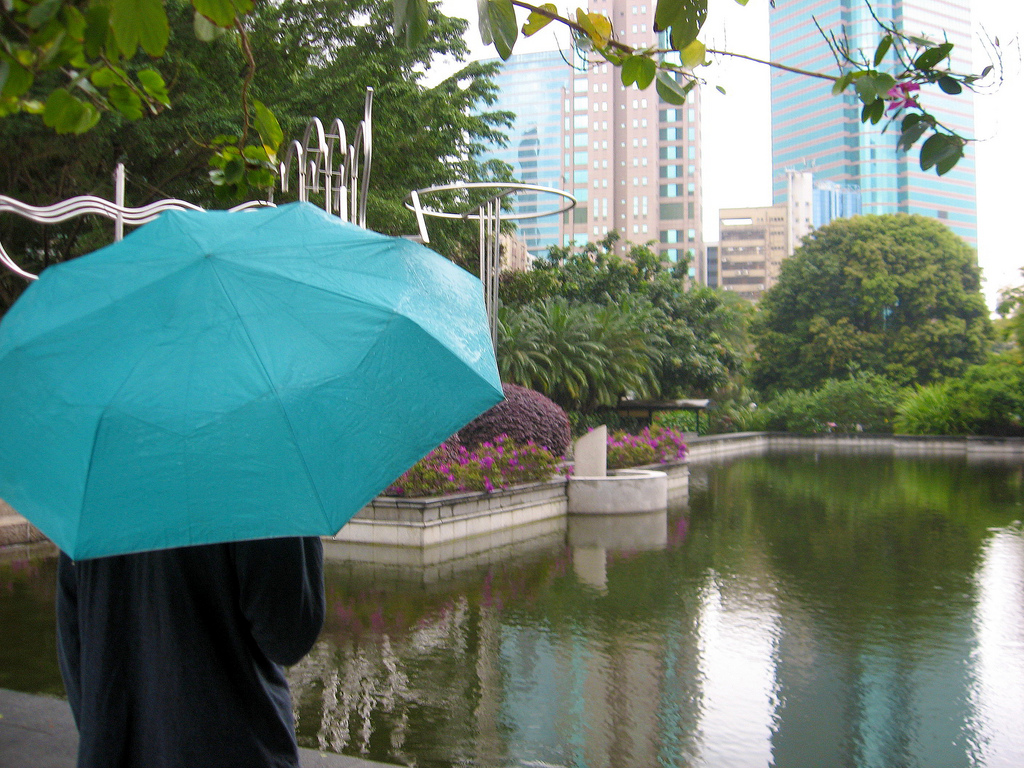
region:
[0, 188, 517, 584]
an umbrella color green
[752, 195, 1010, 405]
a big bush color green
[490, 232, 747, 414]
a big bush color green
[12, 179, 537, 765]
person holding an umbrella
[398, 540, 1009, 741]
reflection on the water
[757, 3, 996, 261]
the building is tall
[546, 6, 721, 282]
the building is red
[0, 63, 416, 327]
silver structure behind an umbrella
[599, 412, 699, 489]
the flowers are pink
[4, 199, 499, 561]
blue umbrella covering person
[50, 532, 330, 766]
person wearing dark blue jacket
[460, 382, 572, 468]
round purple bush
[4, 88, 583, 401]
shiny, silver sculpture with a circular thing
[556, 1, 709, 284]
tall beige building with shiny windows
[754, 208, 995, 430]
bush is large, green and round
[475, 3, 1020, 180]
branch with pink flower at the end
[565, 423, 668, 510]
round stone circle with a white pillar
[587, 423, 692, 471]
small bush with purple flowers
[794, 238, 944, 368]
a bush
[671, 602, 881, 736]
the water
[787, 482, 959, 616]
reflection in the water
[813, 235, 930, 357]
the bush is green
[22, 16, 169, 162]
leaves on the tree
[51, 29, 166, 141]
the leaves are green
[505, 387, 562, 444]
a purple bush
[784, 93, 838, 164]
windows on the building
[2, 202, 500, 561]
aqua canopy of an umbrella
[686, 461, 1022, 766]
reflection of light on the water of a pond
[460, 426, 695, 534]
purple flowers in a stone planter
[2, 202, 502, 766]
person holding an aqua umbrella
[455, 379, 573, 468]
purple hedge trimmed into a round shape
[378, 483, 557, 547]
a pond built of beige stones and bricks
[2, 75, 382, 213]
decorative metal craft displayed in the garden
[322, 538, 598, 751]
a reflection of the purple flowers in the water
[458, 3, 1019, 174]
a tree branch with a purple flower blooming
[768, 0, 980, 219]
a tall building with many windows behind the trees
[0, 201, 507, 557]
open teal umbrella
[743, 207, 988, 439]
large circular shaped tree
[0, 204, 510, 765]
person standing with umbrella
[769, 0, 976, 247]
skyscraper in blue and tan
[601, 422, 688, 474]
row of red flower bushes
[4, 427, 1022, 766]
pond with cement borders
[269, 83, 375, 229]
silver metal scuplture with many curves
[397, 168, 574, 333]
metal sculpture with circle at top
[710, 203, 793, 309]
small brown business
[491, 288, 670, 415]
large leafy tree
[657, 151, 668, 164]
building has a window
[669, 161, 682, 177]
building has a window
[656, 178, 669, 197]
building has a window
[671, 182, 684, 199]
building has a window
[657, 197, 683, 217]
building has a window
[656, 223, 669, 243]
building has a window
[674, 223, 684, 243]
building has a window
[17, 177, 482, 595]
umbrella is held by person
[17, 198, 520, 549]
umbrella is blue in color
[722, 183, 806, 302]
building is red in color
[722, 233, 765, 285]
building has windows on the side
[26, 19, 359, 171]
trees have leaves on them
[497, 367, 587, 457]
bushes with purple flowers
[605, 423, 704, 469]
bushes have pink flowers on them